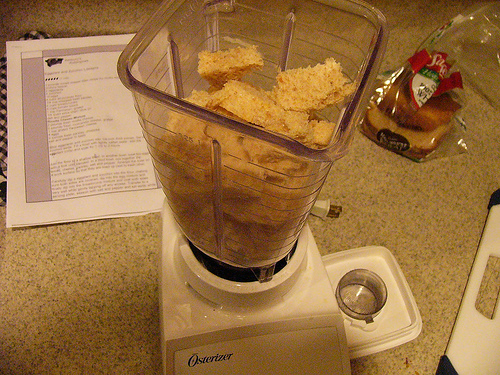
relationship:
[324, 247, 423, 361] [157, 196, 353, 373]
top next to blender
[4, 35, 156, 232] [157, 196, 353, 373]
sheet behind blender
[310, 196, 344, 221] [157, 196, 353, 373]
plug behind blender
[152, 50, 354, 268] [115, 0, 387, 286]
bread inside jar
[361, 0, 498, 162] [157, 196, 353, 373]
bag behind blender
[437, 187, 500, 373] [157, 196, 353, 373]
board to right of blender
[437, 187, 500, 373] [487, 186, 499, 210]
board has corner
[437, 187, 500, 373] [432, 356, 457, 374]
board has corner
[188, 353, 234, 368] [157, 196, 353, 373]
logo on front of blender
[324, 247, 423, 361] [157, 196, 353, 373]
top belongs to blender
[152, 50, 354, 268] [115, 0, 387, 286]
bread inside of jar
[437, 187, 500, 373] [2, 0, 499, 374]
board on counter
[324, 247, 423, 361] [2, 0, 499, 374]
top on counter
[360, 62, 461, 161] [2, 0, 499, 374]
bread on counter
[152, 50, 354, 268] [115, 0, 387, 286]
bread in jar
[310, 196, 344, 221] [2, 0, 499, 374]
plug on top of counter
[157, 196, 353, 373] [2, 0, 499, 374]
blender on top of counter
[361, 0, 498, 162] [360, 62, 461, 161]
bag holds bread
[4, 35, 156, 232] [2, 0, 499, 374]
sheet on counter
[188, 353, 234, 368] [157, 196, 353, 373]
logo on side of blender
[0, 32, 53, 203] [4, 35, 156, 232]
cloth under sheet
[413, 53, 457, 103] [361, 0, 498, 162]
writing on bag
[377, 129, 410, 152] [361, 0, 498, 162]
writing on bag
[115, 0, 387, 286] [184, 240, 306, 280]
jar has ring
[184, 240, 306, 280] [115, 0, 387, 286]
ring underneath jar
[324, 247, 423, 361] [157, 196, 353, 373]
top beside blender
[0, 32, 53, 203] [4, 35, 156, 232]
cloth beneath sheet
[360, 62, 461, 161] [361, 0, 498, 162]
bread in bag